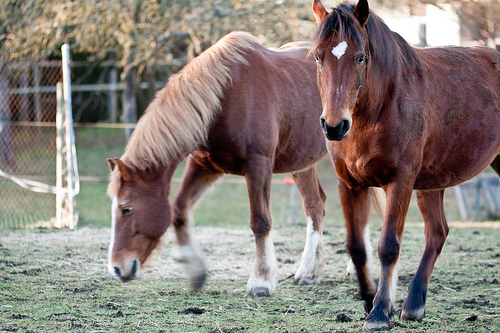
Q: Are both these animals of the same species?
A: Yes, all the animals are horses.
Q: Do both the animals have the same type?
A: Yes, all the animals are horses.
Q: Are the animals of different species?
A: No, all the animals are horses.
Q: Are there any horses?
A: Yes, there is a horse.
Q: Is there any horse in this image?
A: Yes, there is a horse.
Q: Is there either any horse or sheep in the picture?
A: Yes, there is a horse.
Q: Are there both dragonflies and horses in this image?
A: No, there is a horse but no dragonflies.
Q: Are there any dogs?
A: No, there are no dogs.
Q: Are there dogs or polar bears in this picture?
A: No, there are no dogs or polar bears.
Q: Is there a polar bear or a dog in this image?
A: No, there are no dogs or polar bears.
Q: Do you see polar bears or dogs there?
A: No, there are no dogs or polar bears.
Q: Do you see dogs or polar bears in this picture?
A: No, there are no dogs or polar bears.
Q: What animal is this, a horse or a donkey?
A: This is a horse.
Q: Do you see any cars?
A: No, there are no cars.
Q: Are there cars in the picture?
A: No, there are no cars.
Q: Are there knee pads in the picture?
A: No, there are no knee pads.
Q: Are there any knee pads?
A: No, there are no knee pads.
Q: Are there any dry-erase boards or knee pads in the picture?
A: No, there are no knee pads or dry-erase boards.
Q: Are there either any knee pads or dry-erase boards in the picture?
A: No, there are no knee pads or dry-erase boards.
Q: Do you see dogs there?
A: No, there are no dogs.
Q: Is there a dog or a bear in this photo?
A: No, there are no dogs or bears.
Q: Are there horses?
A: Yes, there is a horse.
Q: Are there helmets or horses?
A: Yes, there is a horse.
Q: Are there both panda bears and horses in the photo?
A: No, there is a horse but no panda bears.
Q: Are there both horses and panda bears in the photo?
A: No, there is a horse but no panda bears.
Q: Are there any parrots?
A: No, there are no parrots.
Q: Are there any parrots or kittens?
A: No, there are no parrots or kittens.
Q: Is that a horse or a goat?
A: That is a horse.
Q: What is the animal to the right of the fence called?
A: The animal is a horse.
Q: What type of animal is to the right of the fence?
A: The animal is a horse.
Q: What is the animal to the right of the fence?
A: The animal is a horse.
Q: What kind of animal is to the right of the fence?
A: The animal is a horse.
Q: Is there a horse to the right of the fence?
A: Yes, there is a horse to the right of the fence.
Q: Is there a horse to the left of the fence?
A: No, the horse is to the right of the fence.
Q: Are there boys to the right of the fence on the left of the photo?
A: No, there is a horse to the right of the fence.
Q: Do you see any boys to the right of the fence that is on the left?
A: No, there is a horse to the right of the fence.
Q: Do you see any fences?
A: Yes, there is a fence.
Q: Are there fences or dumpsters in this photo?
A: Yes, there is a fence.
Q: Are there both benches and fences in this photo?
A: No, there is a fence but no benches.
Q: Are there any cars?
A: No, there are no cars.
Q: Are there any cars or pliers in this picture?
A: No, there are no cars or pliers.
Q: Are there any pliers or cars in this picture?
A: No, there are no cars or pliers.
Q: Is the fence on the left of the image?
A: Yes, the fence is on the left of the image.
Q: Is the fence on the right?
A: No, the fence is on the left of the image.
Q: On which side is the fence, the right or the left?
A: The fence is on the left of the image.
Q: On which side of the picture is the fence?
A: The fence is on the left of the image.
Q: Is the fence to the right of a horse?
A: No, the fence is to the left of a horse.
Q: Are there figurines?
A: No, there are no figurines.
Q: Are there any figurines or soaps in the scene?
A: No, there are no figurines or soaps.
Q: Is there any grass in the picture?
A: Yes, there is grass.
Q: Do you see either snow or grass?
A: Yes, there is grass.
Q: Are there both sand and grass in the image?
A: No, there is grass but no sand.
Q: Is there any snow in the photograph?
A: No, there is no snow.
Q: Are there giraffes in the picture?
A: No, there are no giraffes.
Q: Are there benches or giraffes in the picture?
A: No, there are no giraffes or benches.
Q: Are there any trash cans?
A: No, there are no trash cans.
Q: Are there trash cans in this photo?
A: No, there are no trash cans.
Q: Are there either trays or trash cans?
A: No, there are no trash cans or trays.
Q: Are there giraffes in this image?
A: No, there are no giraffes.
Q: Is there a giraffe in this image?
A: No, there are no giraffes.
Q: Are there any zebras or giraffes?
A: No, there are no giraffes or zebras.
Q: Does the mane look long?
A: Yes, the mane is long.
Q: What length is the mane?
A: The mane is long.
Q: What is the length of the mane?
A: The mane is long.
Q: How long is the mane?
A: The mane is long.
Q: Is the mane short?
A: No, the mane is long.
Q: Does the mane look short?
A: No, the mane is long.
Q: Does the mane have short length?
A: No, the mane is long.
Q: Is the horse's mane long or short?
A: The mane is long.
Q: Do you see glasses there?
A: No, there are no glasses.